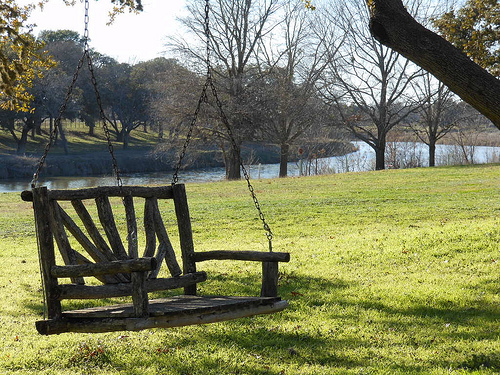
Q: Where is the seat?
A: In the grass.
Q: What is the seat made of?
A: Wood.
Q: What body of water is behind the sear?
A: A lake.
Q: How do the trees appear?
A: Bare.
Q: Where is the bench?
A: Hanging from the tree.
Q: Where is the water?
A: In between two landmasses.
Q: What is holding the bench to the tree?
A: Chains.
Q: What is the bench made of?
A: Wood.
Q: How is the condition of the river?
A: Calm.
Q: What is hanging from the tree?
A: A swing.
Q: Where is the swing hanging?
A: On a tree branch.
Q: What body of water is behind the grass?
A: A river.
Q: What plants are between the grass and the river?
A: Trees.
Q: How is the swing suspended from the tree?
A: With chains.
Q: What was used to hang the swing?
A: Chains.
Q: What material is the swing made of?
A: Wood.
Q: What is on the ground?
A: Green grass.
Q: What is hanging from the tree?
A: A swinging bench.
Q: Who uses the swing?
A: Visitors to the park.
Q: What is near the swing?
A: A body of water.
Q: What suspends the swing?
A: Chains.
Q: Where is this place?
A: A park.